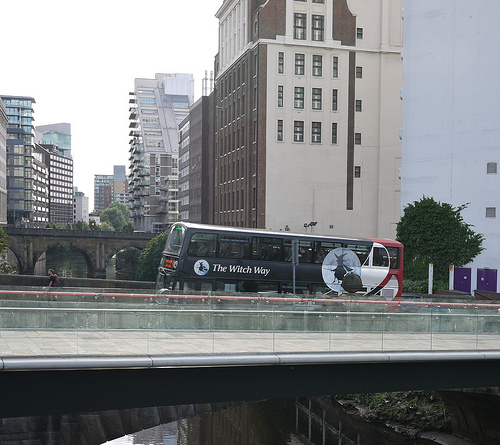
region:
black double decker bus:
[154, 220, 404, 305]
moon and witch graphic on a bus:
[191, 257, 211, 274]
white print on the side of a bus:
[209, 261, 227, 275]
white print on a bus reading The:
[210, 260, 227, 274]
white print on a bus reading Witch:
[226, 262, 253, 275]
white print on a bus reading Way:
[251, 265, 271, 277]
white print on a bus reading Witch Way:
[227, 262, 271, 277]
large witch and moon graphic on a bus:
[320, 244, 365, 292]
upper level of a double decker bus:
[180, 220, 403, 274]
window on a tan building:
[293, 51, 308, 76]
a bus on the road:
[131, 174, 447, 303]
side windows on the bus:
[160, 200, 377, 278]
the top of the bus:
[153, 208, 415, 268]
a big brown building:
[194, 60, 418, 223]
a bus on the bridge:
[93, 169, 464, 421]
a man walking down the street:
[39, 233, 106, 305]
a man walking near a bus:
[27, 178, 357, 307]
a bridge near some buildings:
[18, 168, 285, 280]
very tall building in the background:
[14, 64, 241, 270]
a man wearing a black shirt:
[41, 264, 73, 301]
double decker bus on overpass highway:
[153, 219, 407, 304]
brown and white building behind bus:
[176, 3, 401, 243]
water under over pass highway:
[0, 396, 434, 444]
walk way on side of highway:
[1, 329, 498, 354]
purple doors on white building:
[454, 268, 469, 294]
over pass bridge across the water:
[1, 227, 156, 277]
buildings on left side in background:
[1, 95, 74, 227]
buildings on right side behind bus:
[129, 1, 492, 231]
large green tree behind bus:
[397, 199, 479, 293]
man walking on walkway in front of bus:
[45, 270, 59, 285]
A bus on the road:
[158, 225, 401, 300]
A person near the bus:
[44, 270, 58, 286]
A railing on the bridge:
[0, 313, 498, 356]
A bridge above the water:
[1, 275, 499, 380]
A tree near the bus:
[400, 201, 479, 276]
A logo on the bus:
[192, 263, 272, 275]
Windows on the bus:
[187, 228, 397, 267]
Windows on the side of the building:
[276, 53, 338, 143]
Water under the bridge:
[107, 412, 213, 442]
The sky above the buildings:
[0, 0, 219, 186]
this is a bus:
[110, 217, 420, 314]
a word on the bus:
[202, 255, 234, 280]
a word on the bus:
[223, 251, 253, 286]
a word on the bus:
[251, 259, 275, 286]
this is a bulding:
[9, 98, 33, 248]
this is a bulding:
[33, 120, 90, 237]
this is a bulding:
[76, 148, 133, 225]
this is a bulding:
[109, 56, 206, 255]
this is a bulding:
[207, 0, 409, 251]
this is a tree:
[392, 165, 487, 292]